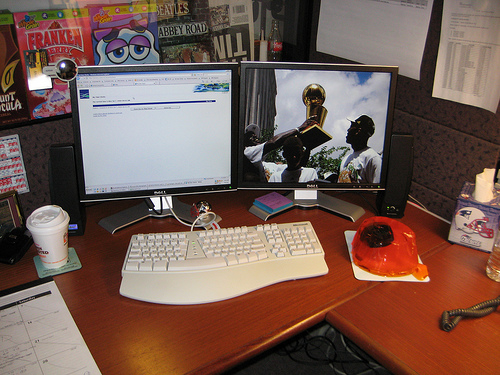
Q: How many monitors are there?
A: Two.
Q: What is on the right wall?
A: A bulletin board.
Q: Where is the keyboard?
A: On the desktop.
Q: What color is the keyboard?
A: White.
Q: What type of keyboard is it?
A: Ergonomic.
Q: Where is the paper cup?
A: On the desktop, left.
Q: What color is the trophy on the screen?
A: Gold.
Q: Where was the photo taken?
A: At a workstation.